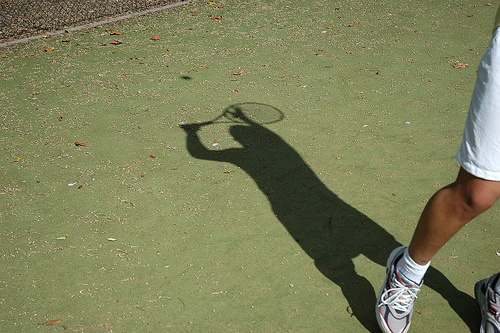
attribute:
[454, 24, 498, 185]
shorts — white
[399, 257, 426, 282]
socks — white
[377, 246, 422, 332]
shoe — athletic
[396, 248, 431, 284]
sock — white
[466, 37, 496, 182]
shorts — white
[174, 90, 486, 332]
shadow — tennis player's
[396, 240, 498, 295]
socks — white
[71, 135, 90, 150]
leaf — small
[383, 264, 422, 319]
laces — white